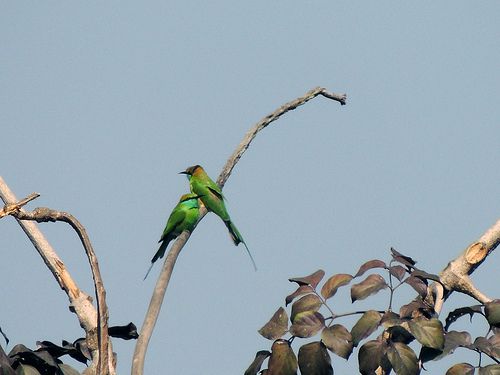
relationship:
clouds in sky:
[0, 0, 500, 164] [328, 51, 469, 164]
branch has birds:
[234, 63, 361, 142] [150, 159, 247, 254]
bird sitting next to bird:
[147, 189, 204, 243] [169, 160, 234, 237]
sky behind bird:
[350, 47, 490, 98] [181, 160, 260, 274]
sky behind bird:
[350, 47, 490, 98] [144, 189, 197, 278]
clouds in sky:
[190, 290, 283, 347] [9, 9, 472, 334]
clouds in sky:
[0, 0, 500, 164] [9, 9, 472, 334]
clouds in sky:
[0, 0, 500, 164] [0, 15, 493, 370]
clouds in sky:
[392, 31, 459, 112] [16, 3, 492, 160]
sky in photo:
[363, 7, 482, 212] [5, 4, 480, 361]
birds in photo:
[120, 159, 251, 261] [5, 4, 480, 361]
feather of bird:
[225, 220, 265, 283] [181, 160, 260, 274]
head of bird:
[179, 159, 204, 179] [180, 160, 254, 261]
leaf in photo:
[319, 267, 359, 299] [5, 4, 480, 361]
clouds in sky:
[191, 78, 331, 164] [9, 9, 472, 334]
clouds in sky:
[0, 0, 500, 164] [379, 127, 474, 198]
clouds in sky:
[0, 0, 500, 164] [1, 1, 498, 140]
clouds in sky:
[392, 31, 459, 112] [9, 10, 465, 250]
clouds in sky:
[0, 0, 500, 164] [3, 15, 467, 207]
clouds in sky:
[0, 0, 500, 164] [340, 47, 496, 85]